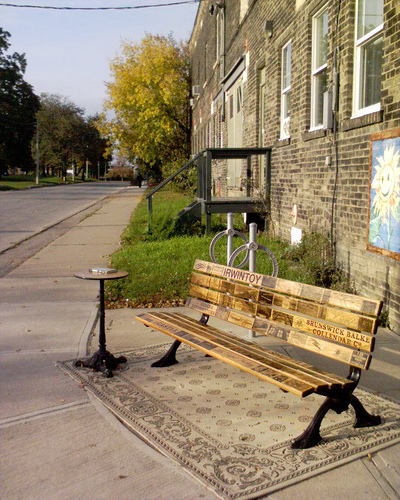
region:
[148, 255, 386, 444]
wood bench with metal legs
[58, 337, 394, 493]
rug on pavement under bench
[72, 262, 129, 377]
circular table on corner of carpet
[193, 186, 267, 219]
platform in front of door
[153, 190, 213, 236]
stairs leading to door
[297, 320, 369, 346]
words on bench back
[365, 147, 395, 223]
painting of flower with face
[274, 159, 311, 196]
bricks on building wall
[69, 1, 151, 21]
wire hanging from building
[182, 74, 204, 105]
air conditioner in building window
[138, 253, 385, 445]
wooden bench sitting on the ground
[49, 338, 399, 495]
carpet rug underneath bench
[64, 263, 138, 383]
table stand sitting on ground by bench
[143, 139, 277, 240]
stairs to a building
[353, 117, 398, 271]
sunflower painting on brick wall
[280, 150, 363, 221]
brick wall of a building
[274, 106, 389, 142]
three windows of a building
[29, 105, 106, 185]
trees along side of street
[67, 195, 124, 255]
concrete sidewalk along the side of road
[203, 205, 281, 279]
silver metal bike racks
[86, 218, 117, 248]
part of a footpath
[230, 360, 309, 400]
edge of a bench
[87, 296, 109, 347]
part of a stand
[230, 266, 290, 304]
surface of a bench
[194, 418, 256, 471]
part of a carpet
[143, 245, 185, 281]
part of some grass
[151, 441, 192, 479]
edge of a carpet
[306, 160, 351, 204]
part of a wall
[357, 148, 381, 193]
part of a picture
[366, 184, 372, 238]
edge of the picture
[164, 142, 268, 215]
this is a staircase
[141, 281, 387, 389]
this is a bench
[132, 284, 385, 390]
the bench is empty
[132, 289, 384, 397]
the bench is wooden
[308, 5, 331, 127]
this is a window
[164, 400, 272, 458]
this is a carpet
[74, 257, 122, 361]
this is a table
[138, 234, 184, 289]
the grass is treamed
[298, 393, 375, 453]
the legs are black in color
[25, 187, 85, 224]
the road is clear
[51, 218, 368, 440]
wooden bench on street corner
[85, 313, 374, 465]
wooden bench on top of rug on street corner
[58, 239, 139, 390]
small table near wooden bench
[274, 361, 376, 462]
wooden bench with black metal legs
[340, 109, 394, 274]
sunshine painting on brick wall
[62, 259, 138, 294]
small table with round top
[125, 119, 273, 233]
wooden stairway leading to building entrance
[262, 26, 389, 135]
windows on brick building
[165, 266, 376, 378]
writing design on bench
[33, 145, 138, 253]
sidewalk in the background